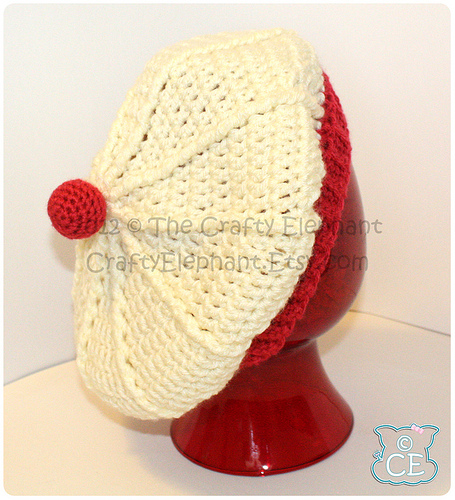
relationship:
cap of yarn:
[32, 28, 335, 416] [307, 74, 354, 249]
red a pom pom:
[307, 72, 371, 269] [38, 177, 117, 237]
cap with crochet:
[32, 28, 335, 416] [264, 37, 309, 99]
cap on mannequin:
[32, 28, 335, 416] [173, 159, 389, 464]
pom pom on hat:
[38, 177, 117, 237] [45, 26, 366, 427]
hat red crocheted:
[45, 26, 366, 427] [265, 31, 326, 177]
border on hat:
[236, 52, 362, 394] [45, 26, 366, 427]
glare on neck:
[264, 350, 346, 426] [159, 341, 361, 475]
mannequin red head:
[173, 159, 389, 464] [244, 176, 391, 360]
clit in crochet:
[107, 32, 294, 137] [264, 37, 309, 99]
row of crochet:
[217, 52, 259, 103] [264, 37, 309, 99]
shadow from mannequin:
[123, 319, 448, 495] [173, 159, 389, 464]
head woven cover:
[244, 176, 391, 360] [36, 24, 334, 399]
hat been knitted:
[45, 26, 366, 427] [107, 40, 293, 161]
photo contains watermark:
[6, 12, 449, 462] [363, 417, 445, 491]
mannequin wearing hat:
[173, 159, 389, 464] [45, 26, 366, 427]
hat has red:
[45, 26, 366, 427] [307, 72, 371, 269]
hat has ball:
[45, 26, 366, 427] [42, 176, 120, 236]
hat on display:
[45, 26, 366, 427] [33, 19, 387, 474]